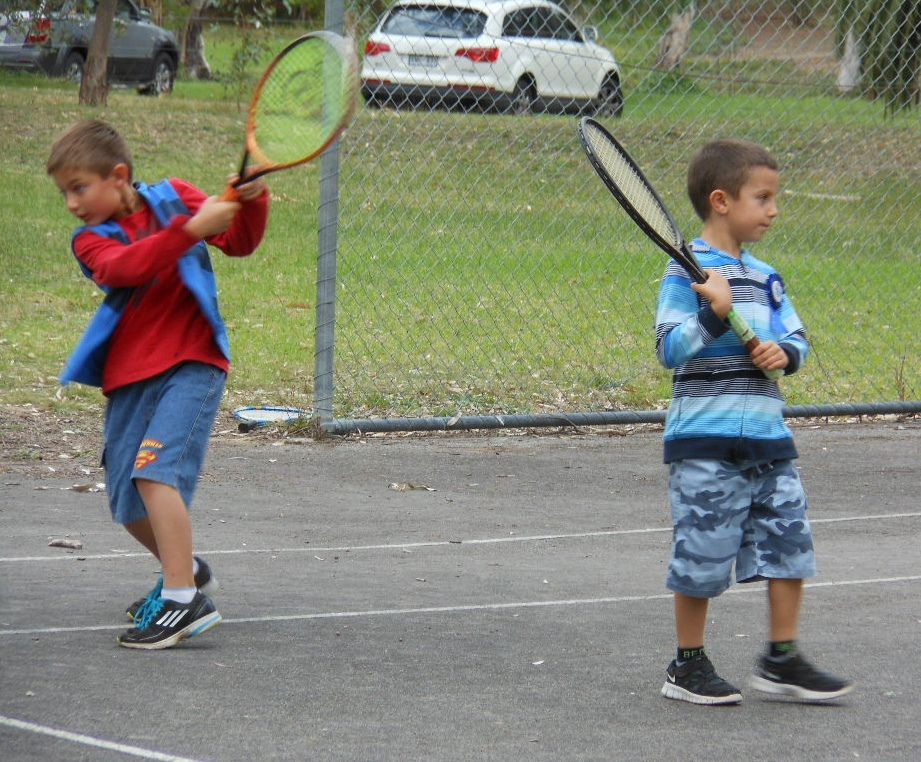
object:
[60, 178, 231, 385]
vest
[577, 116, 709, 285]
racket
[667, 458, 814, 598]
shorts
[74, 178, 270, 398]
shirt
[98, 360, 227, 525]
shorts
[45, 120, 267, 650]
boy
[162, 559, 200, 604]
socks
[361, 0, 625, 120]
suv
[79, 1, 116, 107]
tree trunk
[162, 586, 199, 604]
sock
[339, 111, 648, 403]
grass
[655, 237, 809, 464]
shirt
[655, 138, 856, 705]
boy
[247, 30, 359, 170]
racket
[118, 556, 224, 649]
shoes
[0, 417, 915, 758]
court